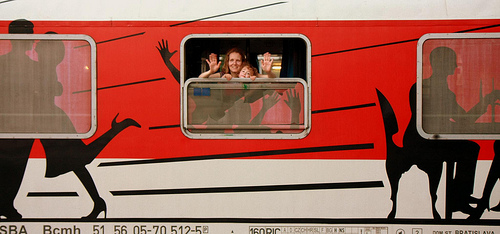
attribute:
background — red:
[104, 44, 412, 179]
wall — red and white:
[2, 1, 494, 232]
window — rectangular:
[176, 32, 311, 137]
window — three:
[410, 25, 487, 141]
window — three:
[172, 26, 317, 148]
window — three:
[2, 28, 102, 148]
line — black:
[336, 95, 368, 120]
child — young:
[194, 62, 256, 121]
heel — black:
[78, 97, 146, 212]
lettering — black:
[96, 217, 250, 232]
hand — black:
[146, 31, 178, 78]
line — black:
[164, 134, 356, 225]